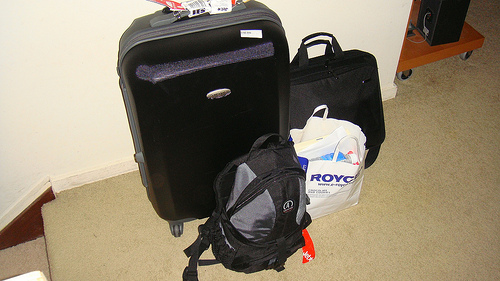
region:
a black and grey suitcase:
[110, 0, 298, 238]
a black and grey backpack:
[193, 137, 318, 272]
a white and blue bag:
[291, 109, 383, 229]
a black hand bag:
[274, 25, 399, 177]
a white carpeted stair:
[0, 243, 52, 279]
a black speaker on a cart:
[413, 1, 472, 51]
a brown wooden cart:
[393, 0, 486, 86]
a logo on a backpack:
[281, 198, 296, 218]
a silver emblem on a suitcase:
[203, 80, 235, 108]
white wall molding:
[48, 70, 403, 195]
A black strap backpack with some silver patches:
[183, 132, 310, 279]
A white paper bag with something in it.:
[289, 104, 368, 219]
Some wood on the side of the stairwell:
[0, 183, 58, 248]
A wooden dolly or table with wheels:
[395, 0, 483, 80]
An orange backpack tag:
[300, 226, 315, 261]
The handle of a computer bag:
[295, 32, 345, 69]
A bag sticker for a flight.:
[180, 0, 207, 16]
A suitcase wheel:
[167, 220, 183, 236]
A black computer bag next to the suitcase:
[285, 31, 385, 166]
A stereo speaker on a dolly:
[416, 0, 469, 47]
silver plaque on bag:
[196, 80, 240, 110]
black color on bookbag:
[266, 159, 278, 167]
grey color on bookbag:
[251, 206, 263, 233]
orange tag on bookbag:
[305, 239, 313, 252]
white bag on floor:
[328, 198, 342, 208]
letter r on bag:
[309, 169, 321, 186]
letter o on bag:
[323, 171, 332, 183]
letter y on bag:
[333, 170, 345, 183]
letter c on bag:
[344, 174, 354, 186]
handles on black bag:
[300, 30, 337, 58]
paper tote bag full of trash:
[290, 101, 369, 226]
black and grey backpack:
[170, 125, 314, 278]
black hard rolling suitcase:
[110, 1, 297, 240]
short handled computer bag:
[287, 26, 384, 173]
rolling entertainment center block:
[395, 14, 487, 84]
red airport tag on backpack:
[298, 220, 317, 263]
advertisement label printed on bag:
[308, 168, 359, 203]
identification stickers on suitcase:
[145, 0, 243, 21]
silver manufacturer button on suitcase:
[202, 85, 233, 100]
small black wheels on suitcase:
[169, 218, 183, 238]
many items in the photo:
[61, 16, 405, 251]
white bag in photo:
[266, 106, 377, 234]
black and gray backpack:
[219, 140, 312, 247]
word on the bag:
[291, 159, 363, 201]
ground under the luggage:
[348, 189, 445, 261]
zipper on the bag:
[203, 167, 281, 234]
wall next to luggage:
[35, 51, 105, 122]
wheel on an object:
[451, 39, 483, 73]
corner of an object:
[466, 21, 495, 55]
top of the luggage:
[104, 2, 264, 68]